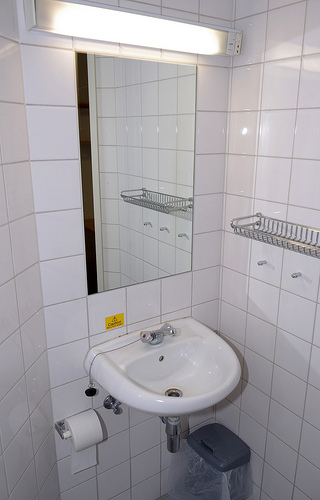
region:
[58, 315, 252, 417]
Sink is white color.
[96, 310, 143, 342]
Sticker is yellow and black color.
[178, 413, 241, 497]
trash is grey color.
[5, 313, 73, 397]
Wall is white color.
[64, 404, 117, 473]
Tissue roll is white color.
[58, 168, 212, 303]
Mirror is attached to the wall.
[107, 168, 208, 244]
reflection is seen in mirror.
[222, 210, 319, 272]
Soap dish is silver color.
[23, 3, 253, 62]
Light is on.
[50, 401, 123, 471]
Tissue holder is fixed to the wall.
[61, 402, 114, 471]
toilet paper on the wall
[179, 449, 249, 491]
Garbage bag in the can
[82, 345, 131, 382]
Chain on the sink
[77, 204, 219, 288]
mirror over a sink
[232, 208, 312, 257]
shelf on the wall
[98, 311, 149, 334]
yellow sinker on the wall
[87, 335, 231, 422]
Sink on the wall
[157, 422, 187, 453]
Drain on the sink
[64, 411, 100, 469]
white roll of toilet tissue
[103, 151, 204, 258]
shelf in the mirror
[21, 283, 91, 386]
Wall is white color.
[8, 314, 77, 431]
Wall is made of tiles.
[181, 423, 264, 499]
Trash is grey color.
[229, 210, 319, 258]
silver rack on the wall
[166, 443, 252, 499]
clear plastic trash bag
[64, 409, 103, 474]
roll of toilet paper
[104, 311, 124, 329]
yellow caution sign on the wall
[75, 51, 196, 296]
mirror on the wall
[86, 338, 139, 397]
black plug on a chain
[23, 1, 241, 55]
light in white holder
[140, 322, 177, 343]
silver faucet in the sink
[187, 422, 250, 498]
blue plastic garbage can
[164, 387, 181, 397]
rusty silver drain in the sink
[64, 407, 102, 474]
the roll of toilet paper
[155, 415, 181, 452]
the pipe under the sink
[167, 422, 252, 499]
the trash can under the sink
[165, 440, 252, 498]
the plastic bag in the trash can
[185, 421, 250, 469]
the lid to the trash can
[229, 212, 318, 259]
the metal shelf on wall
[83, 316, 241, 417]
the white bathroom sink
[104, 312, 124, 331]
the yellow sticker on the wall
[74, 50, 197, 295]
the mirror on the wall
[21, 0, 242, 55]
the light at the top of the mirror